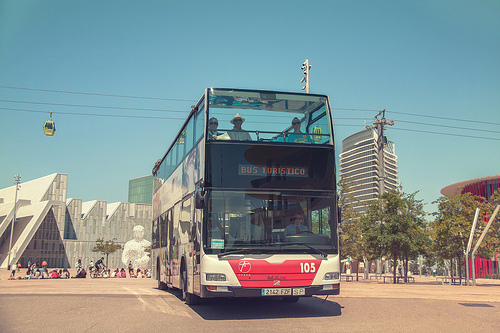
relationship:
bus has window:
[148, 85, 341, 303] [203, 187, 337, 254]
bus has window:
[148, 85, 341, 303] [273, 191, 338, 249]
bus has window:
[148, 85, 341, 303] [205, 86, 337, 149]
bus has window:
[148, 85, 341, 303] [208, 87, 334, 142]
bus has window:
[148, 85, 341, 303] [193, 93, 210, 148]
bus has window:
[148, 85, 341, 307] [153, 198, 203, 260]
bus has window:
[148, 85, 341, 307] [207, 95, 306, 138]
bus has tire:
[148, 85, 341, 307] [149, 253, 164, 290]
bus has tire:
[148, 85, 341, 307] [177, 253, 189, 299]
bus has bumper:
[148, 85, 341, 307] [197, 238, 344, 298]